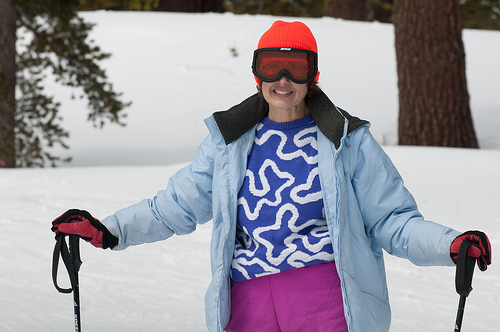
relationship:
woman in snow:
[195, 11, 391, 261] [67, 169, 139, 199]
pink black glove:
[79, 227, 95, 234] [50, 207, 118, 251]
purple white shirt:
[254, 146, 263, 160] [241, 127, 326, 260]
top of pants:
[230, 275, 336, 309] [224, 257, 338, 330]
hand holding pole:
[445, 232, 491, 269] [443, 244, 480, 332]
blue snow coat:
[170, 193, 187, 214] [104, 90, 463, 332]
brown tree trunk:
[409, 36, 426, 59] [392, 2, 481, 149]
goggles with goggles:
[251, 48, 320, 86] [248, 45, 323, 86]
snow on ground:
[67, 169, 139, 199] [102, 11, 207, 145]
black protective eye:
[289, 75, 293, 82] [249, 45, 321, 84]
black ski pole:
[289, 75, 293, 82] [443, 244, 480, 332]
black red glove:
[289, 75, 293, 82] [50, 207, 118, 251]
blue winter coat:
[170, 193, 187, 214] [104, 95, 450, 303]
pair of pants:
[220, 272, 347, 332] [224, 257, 338, 330]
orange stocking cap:
[264, 20, 308, 43] [251, 18, 325, 82]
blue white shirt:
[170, 193, 187, 214] [226, 115, 335, 281]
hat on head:
[256, 19, 318, 53] [246, 15, 330, 125]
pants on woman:
[224, 257, 338, 330] [195, 11, 391, 261]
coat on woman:
[104, 95, 450, 303] [195, 11, 391, 261]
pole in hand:
[443, 244, 480, 332] [445, 232, 491, 269]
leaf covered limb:
[63, 27, 82, 45] [15, 7, 72, 69]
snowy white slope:
[138, 94, 195, 144] [19, 7, 209, 159]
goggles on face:
[251, 48, 320, 86] [254, 43, 311, 107]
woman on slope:
[195, 11, 391, 261] [19, 7, 209, 159]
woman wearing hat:
[195, 11, 391, 261] [256, 19, 318, 53]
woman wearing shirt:
[195, 11, 391, 261] [226, 115, 335, 281]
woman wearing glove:
[195, 11, 391, 261] [50, 207, 118, 251]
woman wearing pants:
[195, 11, 391, 261] [224, 257, 338, 330]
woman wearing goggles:
[195, 11, 391, 261] [251, 48, 320, 86]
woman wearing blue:
[195, 11, 391, 261] [170, 193, 187, 214]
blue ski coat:
[170, 193, 187, 214] [104, 90, 463, 332]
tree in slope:
[389, 3, 483, 147] [19, 7, 209, 159]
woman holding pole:
[195, 11, 391, 261] [443, 244, 480, 332]